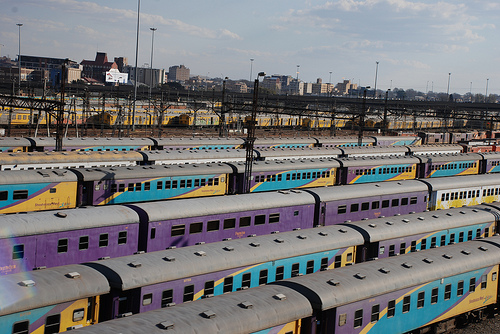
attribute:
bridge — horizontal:
[207, 81, 498, 136]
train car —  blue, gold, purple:
[127, 183, 314, 248]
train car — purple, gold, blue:
[333, 153, 419, 183]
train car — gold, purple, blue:
[306, 247, 497, 332]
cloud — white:
[328, 2, 485, 29]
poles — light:
[111, 7, 156, 143]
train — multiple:
[58, 137, 360, 332]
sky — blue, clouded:
[0, 0, 498, 96]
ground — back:
[405, 164, 453, 192]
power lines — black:
[0, 78, 498, 116]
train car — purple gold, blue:
[82, 172, 228, 202]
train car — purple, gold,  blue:
[231, 155, 341, 189]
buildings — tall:
[0, 54, 498, 105]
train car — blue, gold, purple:
[404, 151, 469, 171]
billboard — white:
[104, 61, 129, 84]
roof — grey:
[0, 201, 140, 235]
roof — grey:
[290, 241, 483, 306]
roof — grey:
[131, 185, 315, 219]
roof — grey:
[307, 179, 428, 198]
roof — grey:
[4, 158, 75, 194]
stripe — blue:
[195, 245, 344, 294]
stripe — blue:
[363, 270, 483, 326]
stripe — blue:
[102, 165, 209, 200]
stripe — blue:
[244, 166, 330, 192]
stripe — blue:
[432, 157, 475, 179]